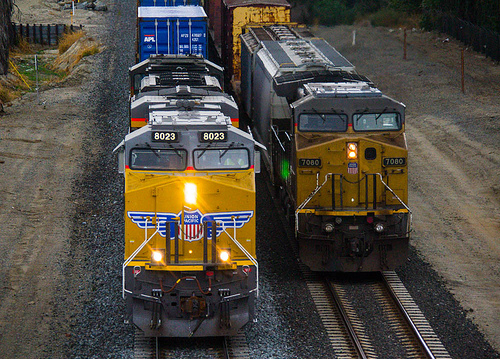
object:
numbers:
[154, 132, 159, 139]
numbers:
[203, 133, 209, 140]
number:
[302, 159, 306, 166]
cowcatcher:
[120, 262, 257, 339]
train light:
[349, 143, 357, 151]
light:
[280, 160, 291, 179]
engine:
[110, 50, 270, 338]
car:
[240, 23, 414, 281]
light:
[219, 251, 229, 261]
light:
[152, 250, 163, 262]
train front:
[112, 120, 267, 339]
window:
[191, 146, 251, 170]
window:
[128, 147, 187, 171]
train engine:
[274, 78, 414, 277]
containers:
[138, 1, 203, 7]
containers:
[220, 0, 290, 98]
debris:
[45, 31, 101, 90]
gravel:
[402, 256, 500, 359]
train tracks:
[53, 339, 129, 359]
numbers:
[159, 133, 164, 141]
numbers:
[306, 160, 311, 166]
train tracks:
[259, 276, 500, 358]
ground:
[0, 0, 500, 359]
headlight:
[184, 183, 197, 203]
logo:
[126, 208, 255, 243]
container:
[135, 5, 209, 63]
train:
[108, 0, 268, 344]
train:
[196, 0, 412, 282]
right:
[245, 0, 500, 359]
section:
[291, 272, 339, 352]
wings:
[127, 210, 178, 241]